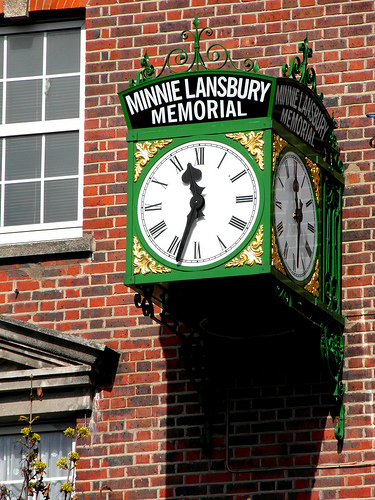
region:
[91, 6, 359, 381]
A picture of a clock.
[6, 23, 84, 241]
A window on a building.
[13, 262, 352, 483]
A red brick building.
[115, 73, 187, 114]
The word MINNIE in white lettering.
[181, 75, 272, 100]
The word LANSBURY in white lettering.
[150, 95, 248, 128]
The word MEMORIAL in white lettering.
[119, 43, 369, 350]
A clock with a green frame.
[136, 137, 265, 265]
A white clock face.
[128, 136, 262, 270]
Roman numerals on a clock.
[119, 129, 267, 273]
Decorative gold design on corner of clock.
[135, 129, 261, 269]
clock reads 11:33 in the morning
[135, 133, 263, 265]
clock face is on a green decorative item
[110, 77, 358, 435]
wall decorative item is mostly green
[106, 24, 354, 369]
decorative item has clocks on it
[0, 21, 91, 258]
window is to the left of the clocks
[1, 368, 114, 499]
weeds are growing in the corner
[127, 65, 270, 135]
sign reads minnie lansbury memorial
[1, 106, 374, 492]
the wall is red brick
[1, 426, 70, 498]
white curtains are hanging in the window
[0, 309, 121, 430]
wood is above the window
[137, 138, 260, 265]
a nice white watch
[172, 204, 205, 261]
a long black arm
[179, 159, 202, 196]
a short black arm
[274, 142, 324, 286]
another white watch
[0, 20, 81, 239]
a window in a building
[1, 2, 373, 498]
a wall made of bricks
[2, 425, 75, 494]
another window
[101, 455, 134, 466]
a brick in a wall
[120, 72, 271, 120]
some white writings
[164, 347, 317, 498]
a shadow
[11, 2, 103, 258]
Window with eight panes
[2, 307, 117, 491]
window with decorative element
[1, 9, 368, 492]
brick wall with windows and clock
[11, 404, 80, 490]
plants with yellow flowers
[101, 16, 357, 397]
Decorative clock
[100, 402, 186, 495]
dark bricks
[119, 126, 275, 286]
clock face on a green background embellished with gold leaf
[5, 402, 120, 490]
Window with white curtains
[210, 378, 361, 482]
electrical wires protected by plastic casing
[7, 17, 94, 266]
window with venetian blinds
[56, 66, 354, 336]
large clock on brick wall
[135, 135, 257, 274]
roman numerals on clock face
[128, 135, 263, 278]
gold leaves in corners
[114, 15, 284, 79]
green iron work in curliques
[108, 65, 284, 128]
sign honoring woman who died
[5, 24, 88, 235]
white window divided by many panes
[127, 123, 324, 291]
two sides of the clock showing the time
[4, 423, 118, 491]
yellow pompom-like flowers on tall stems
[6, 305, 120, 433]
decorative molding over a window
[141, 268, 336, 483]
huge shadow on wall cast by clock